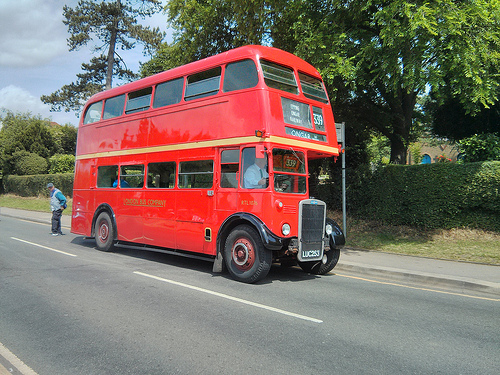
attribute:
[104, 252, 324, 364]
line — white, broken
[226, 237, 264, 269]
hubcap — here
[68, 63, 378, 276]
bus — red, double decker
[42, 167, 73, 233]
person — standing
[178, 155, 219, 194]
window — open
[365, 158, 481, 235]
bushes — here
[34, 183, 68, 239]
man — here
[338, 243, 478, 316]
sidewalk — here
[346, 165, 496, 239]
hedge — green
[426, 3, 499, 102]
leaves — green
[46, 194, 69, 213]
shirt — blue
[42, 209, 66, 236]
pants — black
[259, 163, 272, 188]
tie — black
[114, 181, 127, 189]
shirt — blue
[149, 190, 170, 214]
word — gold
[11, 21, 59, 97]
cloud — white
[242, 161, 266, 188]
shirt — white